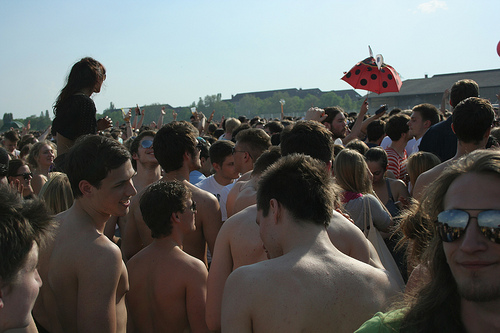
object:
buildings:
[208, 87, 362, 116]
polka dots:
[360, 78, 367, 86]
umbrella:
[340, 45, 403, 105]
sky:
[0, 0, 499, 120]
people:
[1, 57, 499, 332]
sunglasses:
[435, 208, 498, 242]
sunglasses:
[180, 199, 197, 211]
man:
[118, 121, 223, 269]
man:
[192, 140, 241, 269]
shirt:
[193, 173, 243, 262]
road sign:
[278, 99, 285, 121]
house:
[363, 67, 498, 112]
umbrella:
[340, 45, 402, 95]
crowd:
[0, 92, 500, 331]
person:
[50, 57, 113, 171]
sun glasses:
[141, 140, 154, 148]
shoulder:
[222, 260, 288, 318]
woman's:
[325, 148, 395, 248]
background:
[0, 70, 495, 117]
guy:
[32, 136, 138, 333]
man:
[350, 148, 500, 333]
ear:
[172, 210, 180, 223]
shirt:
[378, 146, 413, 198]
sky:
[115, 24, 251, 81]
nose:
[459, 217, 488, 255]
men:
[44, 133, 388, 325]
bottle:
[136, 104, 142, 115]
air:
[19, 0, 499, 330]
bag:
[363, 192, 405, 298]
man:
[120, 178, 211, 331]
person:
[384, 113, 415, 187]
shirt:
[46, 89, 100, 142]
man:
[104, 130, 166, 263]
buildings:
[100, 69, 500, 120]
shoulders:
[83, 231, 125, 280]